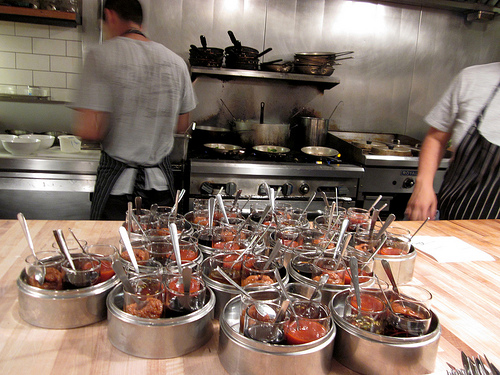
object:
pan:
[301, 146, 340, 157]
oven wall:
[98, 0, 499, 142]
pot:
[250, 122, 290, 146]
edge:
[94, 150, 103, 192]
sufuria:
[215, 255, 452, 375]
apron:
[89, 29, 176, 220]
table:
[0, 220, 498, 375]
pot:
[317, 210, 379, 237]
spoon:
[17, 212, 47, 285]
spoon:
[118, 226, 148, 294]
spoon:
[168, 222, 185, 288]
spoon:
[349, 256, 367, 325]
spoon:
[381, 259, 406, 308]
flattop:
[328, 129, 454, 160]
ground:
[358, 221, 385, 246]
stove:
[188, 146, 365, 212]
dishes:
[25, 212, 427, 345]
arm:
[414, 67, 472, 184]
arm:
[65, 80, 111, 142]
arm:
[177, 57, 197, 134]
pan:
[252, 145, 290, 153]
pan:
[204, 143, 243, 155]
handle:
[273, 267, 299, 325]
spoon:
[274, 267, 300, 331]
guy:
[65, 0, 200, 221]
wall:
[0, 0, 79, 134]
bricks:
[0, 21, 83, 103]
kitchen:
[0, 0, 499, 375]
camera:
[2, 0, 500, 375]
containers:
[16, 200, 442, 375]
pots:
[188, 30, 355, 77]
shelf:
[190, 66, 341, 90]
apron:
[436, 80, 499, 221]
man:
[403, 62, 499, 221]